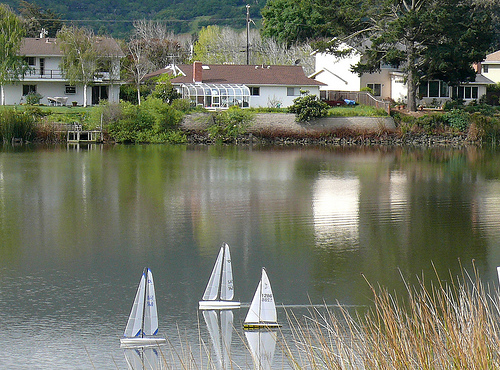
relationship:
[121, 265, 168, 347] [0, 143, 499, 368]
sailboat in water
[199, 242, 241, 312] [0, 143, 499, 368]
sailboat in water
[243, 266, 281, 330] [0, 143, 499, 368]
sailboat in water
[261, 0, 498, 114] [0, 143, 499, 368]
tree next to water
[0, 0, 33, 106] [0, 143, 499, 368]
tree next to water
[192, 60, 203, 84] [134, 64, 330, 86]
chimney on top of roof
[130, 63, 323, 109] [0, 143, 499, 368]
house by river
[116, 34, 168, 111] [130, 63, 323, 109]
tree next to house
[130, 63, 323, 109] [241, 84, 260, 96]
house has window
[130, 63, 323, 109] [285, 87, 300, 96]
house has window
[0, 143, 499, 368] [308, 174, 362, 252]
water has reflection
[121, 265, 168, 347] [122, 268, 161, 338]
boat has sail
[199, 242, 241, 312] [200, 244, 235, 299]
boat has sail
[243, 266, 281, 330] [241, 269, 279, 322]
boat has sail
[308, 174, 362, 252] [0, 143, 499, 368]
reflection in water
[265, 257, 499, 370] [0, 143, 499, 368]
grass near water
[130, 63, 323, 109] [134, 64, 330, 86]
house has roof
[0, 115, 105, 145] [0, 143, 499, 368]
dock near water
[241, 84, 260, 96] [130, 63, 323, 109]
window on side of house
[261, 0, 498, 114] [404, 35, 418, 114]
tree has trunk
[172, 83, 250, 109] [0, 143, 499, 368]
greenhouse near water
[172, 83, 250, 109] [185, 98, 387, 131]
greenhouse in backyard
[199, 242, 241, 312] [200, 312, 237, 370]
sailboat has reflection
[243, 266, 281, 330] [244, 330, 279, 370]
sailboat has reflection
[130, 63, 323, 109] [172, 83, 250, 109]
house has porch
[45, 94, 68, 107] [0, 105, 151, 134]
barbeque in backyard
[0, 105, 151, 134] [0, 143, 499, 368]
yard near water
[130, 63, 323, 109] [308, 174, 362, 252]
house has reflection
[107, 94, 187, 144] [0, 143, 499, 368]
bush next to water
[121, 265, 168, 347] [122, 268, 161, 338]
sailboat has sail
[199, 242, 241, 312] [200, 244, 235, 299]
sailboat has sail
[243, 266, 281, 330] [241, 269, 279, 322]
sailboat has sail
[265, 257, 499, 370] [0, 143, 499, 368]
grass by water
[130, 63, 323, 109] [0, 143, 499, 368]
house next to water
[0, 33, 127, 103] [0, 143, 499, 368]
house next to water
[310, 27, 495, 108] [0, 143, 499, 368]
house next to water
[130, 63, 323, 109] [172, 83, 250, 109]
house has greenhouse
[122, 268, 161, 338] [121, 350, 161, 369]
sail has reflection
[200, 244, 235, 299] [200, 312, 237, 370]
sail has reflection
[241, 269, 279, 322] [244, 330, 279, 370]
sail has reflection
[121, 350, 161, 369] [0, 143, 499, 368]
reflection in water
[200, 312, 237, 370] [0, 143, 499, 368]
reflection in water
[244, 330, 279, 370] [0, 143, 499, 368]
reflection in water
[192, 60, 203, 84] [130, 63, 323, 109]
chimney on top of house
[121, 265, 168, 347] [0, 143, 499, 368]
sailboat on water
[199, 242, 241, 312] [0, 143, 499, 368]
sailboat on water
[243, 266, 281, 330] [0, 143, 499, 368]
sailboat on water